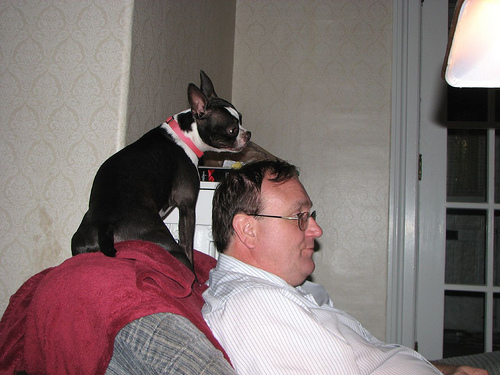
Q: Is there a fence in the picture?
A: No, there are no fences.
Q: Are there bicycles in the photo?
A: No, there are no bicycles.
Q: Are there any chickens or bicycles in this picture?
A: No, there are no bicycles or chickens.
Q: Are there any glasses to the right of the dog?
A: Yes, there are glasses to the right of the dog.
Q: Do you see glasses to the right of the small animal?
A: Yes, there are glasses to the right of the dog.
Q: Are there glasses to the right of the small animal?
A: Yes, there are glasses to the right of the dog.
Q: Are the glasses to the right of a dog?
A: Yes, the glasses are to the right of a dog.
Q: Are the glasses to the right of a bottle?
A: No, the glasses are to the right of a dog.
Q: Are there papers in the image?
A: No, there are no papers.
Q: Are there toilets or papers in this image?
A: No, there are no papers or toilets.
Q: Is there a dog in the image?
A: Yes, there is a dog.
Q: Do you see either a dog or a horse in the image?
A: Yes, there is a dog.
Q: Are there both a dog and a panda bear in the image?
A: No, there is a dog but no panda bears.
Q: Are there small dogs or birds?
A: Yes, there is a small dog.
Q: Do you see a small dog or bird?
A: Yes, there is a small dog.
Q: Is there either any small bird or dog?
A: Yes, there is a small dog.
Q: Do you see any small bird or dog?
A: Yes, there is a small dog.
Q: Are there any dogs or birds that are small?
A: Yes, the dog is small.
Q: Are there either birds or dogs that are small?
A: Yes, the dog is small.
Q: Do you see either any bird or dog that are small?
A: Yes, the dog is small.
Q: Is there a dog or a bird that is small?
A: Yes, the dog is small.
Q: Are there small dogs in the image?
A: Yes, there is a small dog.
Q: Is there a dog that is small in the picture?
A: Yes, there is a small dog.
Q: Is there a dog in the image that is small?
A: Yes, there is a dog that is small.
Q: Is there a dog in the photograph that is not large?
A: Yes, there is a small dog.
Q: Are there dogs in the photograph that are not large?
A: Yes, there is a small dog.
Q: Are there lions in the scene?
A: No, there are no lions.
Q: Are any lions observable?
A: No, there are no lions.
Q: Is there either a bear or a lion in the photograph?
A: No, there are no lions or bears.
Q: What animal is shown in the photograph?
A: The animal is a dog.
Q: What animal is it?
A: The animal is a dog.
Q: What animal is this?
A: This is a dog.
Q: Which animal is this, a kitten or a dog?
A: This is a dog.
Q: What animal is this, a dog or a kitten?
A: This is a dog.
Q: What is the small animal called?
A: The animal is a dog.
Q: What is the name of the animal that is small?
A: The animal is a dog.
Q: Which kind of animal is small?
A: The animal is a dog.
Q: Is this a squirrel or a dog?
A: This is a dog.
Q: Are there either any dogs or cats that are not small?
A: No, there is a dog but it is small.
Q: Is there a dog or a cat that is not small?
A: No, there is a dog but it is small.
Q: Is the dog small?
A: Yes, the dog is small.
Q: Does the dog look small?
A: Yes, the dog is small.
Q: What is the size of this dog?
A: The dog is small.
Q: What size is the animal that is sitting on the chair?
A: The dog is small.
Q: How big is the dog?
A: The dog is small.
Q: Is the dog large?
A: No, the dog is small.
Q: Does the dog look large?
A: No, the dog is small.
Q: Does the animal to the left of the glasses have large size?
A: No, the dog is small.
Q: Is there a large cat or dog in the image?
A: No, there is a dog but it is small.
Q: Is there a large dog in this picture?
A: No, there is a dog but it is small.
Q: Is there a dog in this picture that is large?
A: No, there is a dog but it is small.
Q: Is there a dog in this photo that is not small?
A: No, there is a dog but it is small.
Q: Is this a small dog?
A: Yes, this is a small dog.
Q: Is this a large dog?
A: No, this is a small dog.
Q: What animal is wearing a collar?
A: The dog is wearing a collar.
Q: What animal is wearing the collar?
A: The dog is wearing a collar.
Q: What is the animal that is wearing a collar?
A: The animal is a dog.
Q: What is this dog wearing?
A: The dog is wearing a collar.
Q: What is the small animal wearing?
A: The dog is wearing a collar.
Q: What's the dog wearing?
A: The dog is wearing a collar.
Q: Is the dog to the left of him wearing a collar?
A: Yes, the dog is wearing a collar.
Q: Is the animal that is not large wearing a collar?
A: Yes, the dog is wearing a collar.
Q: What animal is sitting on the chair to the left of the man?
A: The dog is sitting on the chair.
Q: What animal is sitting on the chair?
A: The dog is sitting on the chair.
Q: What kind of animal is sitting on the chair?
A: The animal is a dog.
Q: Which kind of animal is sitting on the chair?
A: The animal is a dog.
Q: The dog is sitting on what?
A: The dog is sitting on the chair.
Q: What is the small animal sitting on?
A: The dog is sitting on the chair.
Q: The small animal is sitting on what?
A: The dog is sitting on the chair.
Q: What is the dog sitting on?
A: The dog is sitting on the chair.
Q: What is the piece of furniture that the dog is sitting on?
A: The piece of furniture is a chair.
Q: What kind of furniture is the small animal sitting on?
A: The dog is sitting on the chair.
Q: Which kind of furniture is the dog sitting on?
A: The dog is sitting on the chair.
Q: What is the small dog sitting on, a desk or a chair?
A: The dog is sitting on a chair.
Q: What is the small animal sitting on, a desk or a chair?
A: The dog is sitting on a chair.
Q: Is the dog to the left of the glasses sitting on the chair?
A: Yes, the dog is sitting on the chair.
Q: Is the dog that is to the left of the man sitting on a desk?
A: No, the dog is sitting on the chair.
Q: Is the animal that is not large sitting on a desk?
A: No, the dog is sitting on the chair.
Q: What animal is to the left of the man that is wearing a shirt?
A: The animal is a dog.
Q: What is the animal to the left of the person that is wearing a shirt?
A: The animal is a dog.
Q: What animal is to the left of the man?
A: The animal is a dog.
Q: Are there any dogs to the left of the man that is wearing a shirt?
A: Yes, there is a dog to the left of the man.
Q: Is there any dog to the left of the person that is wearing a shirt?
A: Yes, there is a dog to the left of the man.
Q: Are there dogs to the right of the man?
A: No, the dog is to the left of the man.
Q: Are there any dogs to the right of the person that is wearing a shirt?
A: No, the dog is to the left of the man.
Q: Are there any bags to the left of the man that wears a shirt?
A: No, there is a dog to the left of the man.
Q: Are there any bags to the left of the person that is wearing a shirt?
A: No, there is a dog to the left of the man.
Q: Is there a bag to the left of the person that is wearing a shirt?
A: No, there is a dog to the left of the man.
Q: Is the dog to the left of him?
A: Yes, the dog is to the left of the man.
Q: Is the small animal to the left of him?
A: Yes, the dog is to the left of the man.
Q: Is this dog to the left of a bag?
A: No, the dog is to the left of the man.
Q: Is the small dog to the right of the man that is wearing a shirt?
A: No, the dog is to the left of the man.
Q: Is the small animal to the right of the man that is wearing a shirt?
A: No, the dog is to the left of the man.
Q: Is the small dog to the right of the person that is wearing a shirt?
A: No, the dog is to the left of the man.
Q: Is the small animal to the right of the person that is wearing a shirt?
A: No, the dog is to the left of the man.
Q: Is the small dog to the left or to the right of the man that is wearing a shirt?
A: The dog is to the left of the man.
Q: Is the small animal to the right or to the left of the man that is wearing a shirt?
A: The dog is to the left of the man.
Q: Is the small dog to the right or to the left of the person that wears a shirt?
A: The dog is to the left of the man.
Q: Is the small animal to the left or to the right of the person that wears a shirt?
A: The dog is to the left of the man.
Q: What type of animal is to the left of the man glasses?
A: The animal is a dog.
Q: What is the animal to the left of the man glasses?
A: The animal is a dog.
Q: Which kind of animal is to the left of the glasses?
A: The animal is a dog.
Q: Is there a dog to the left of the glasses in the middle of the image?
A: Yes, there is a dog to the left of the glasses.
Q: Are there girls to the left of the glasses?
A: No, there is a dog to the left of the glasses.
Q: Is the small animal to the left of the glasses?
A: Yes, the dog is to the left of the glasses.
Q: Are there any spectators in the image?
A: No, there are no spectators.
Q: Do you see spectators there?
A: No, there are no spectators.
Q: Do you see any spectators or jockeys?
A: No, there are no spectators or jockeys.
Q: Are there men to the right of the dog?
A: Yes, there is a man to the right of the dog.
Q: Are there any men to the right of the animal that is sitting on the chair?
A: Yes, there is a man to the right of the dog.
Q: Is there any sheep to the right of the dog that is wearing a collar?
A: No, there is a man to the right of the dog.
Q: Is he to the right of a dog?
A: Yes, the man is to the right of a dog.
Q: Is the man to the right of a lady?
A: No, the man is to the right of a dog.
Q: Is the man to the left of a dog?
A: No, the man is to the right of a dog.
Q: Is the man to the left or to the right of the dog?
A: The man is to the right of the dog.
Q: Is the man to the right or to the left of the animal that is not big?
A: The man is to the right of the dog.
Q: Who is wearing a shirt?
A: The man is wearing a shirt.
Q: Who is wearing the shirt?
A: The man is wearing a shirt.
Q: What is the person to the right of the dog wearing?
A: The man is wearing a shirt.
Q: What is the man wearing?
A: The man is wearing a shirt.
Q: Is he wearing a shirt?
A: Yes, the man is wearing a shirt.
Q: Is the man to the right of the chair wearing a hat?
A: No, the man is wearing a shirt.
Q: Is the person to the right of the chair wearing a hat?
A: No, the man is wearing a shirt.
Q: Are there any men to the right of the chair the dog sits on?
A: Yes, there is a man to the right of the chair.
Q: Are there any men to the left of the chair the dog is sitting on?
A: No, the man is to the right of the chair.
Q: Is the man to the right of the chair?
A: Yes, the man is to the right of the chair.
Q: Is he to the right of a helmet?
A: No, the man is to the right of the chair.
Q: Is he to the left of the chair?
A: No, the man is to the right of the chair.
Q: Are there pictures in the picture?
A: No, there are no pictures.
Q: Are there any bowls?
A: No, there are no bowls.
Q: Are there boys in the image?
A: No, there are no boys.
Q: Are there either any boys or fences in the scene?
A: No, there are no boys or fences.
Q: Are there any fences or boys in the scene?
A: No, there are no boys or fences.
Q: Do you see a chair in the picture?
A: Yes, there is a chair.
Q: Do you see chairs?
A: Yes, there is a chair.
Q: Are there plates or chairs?
A: Yes, there is a chair.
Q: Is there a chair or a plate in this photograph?
A: Yes, there is a chair.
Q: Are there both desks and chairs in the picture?
A: No, there is a chair but no desks.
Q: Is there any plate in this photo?
A: No, there are no plates.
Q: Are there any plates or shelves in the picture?
A: No, there are no plates or shelves.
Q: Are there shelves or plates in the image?
A: No, there are no plates or shelves.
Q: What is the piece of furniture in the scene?
A: The piece of furniture is a chair.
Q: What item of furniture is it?
A: The piece of furniture is a chair.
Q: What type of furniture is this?
A: This is a chair.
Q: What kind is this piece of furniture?
A: This is a chair.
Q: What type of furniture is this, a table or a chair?
A: This is a chair.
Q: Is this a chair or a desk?
A: This is a chair.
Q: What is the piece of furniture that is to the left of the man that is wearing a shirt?
A: The piece of furniture is a chair.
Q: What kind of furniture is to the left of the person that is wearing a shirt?
A: The piece of furniture is a chair.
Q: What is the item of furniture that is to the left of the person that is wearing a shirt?
A: The piece of furniture is a chair.